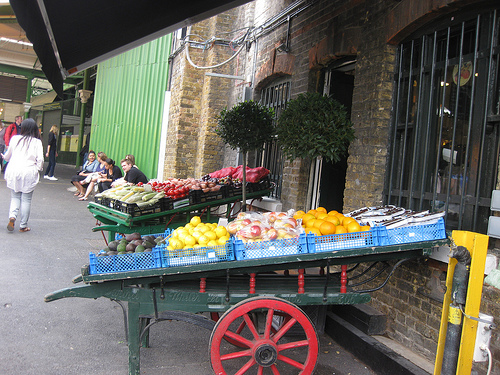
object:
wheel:
[208, 290, 320, 375]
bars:
[399, 185, 494, 227]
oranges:
[291, 207, 372, 239]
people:
[70, 151, 155, 201]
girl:
[4, 111, 44, 232]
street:
[0, 169, 424, 375]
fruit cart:
[41, 199, 446, 373]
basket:
[86, 224, 169, 274]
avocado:
[126, 231, 138, 240]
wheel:
[208, 294, 317, 373]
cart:
[44, 204, 451, 367]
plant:
[273, 90, 356, 209]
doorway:
[311, 66, 353, 215]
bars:
[379, 2, 499, 234]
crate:
[304, 226, 375, 255]